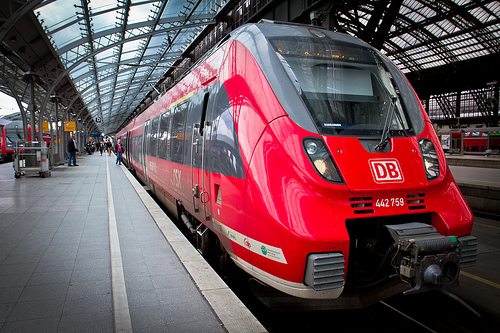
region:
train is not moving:
[117, 23, 479, 303]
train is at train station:
[114, 23, 484, 300]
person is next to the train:
[113, 138, 128, 165]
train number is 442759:
[113, 28, 483, 299]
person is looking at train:
[65, 133, 80, 167]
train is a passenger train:
[116, 21, 485, 310]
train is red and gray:
[121, 34, 483, 306]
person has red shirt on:
[113, 134, 125, 166]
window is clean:
[266, 33, 429, 138]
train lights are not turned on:
[127, 21, 483, 301]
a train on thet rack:
[90, 87, 404, 307]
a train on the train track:
[101, 2, 478, 305]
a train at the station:
[134, 26, 482, 321]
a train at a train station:
[87, 33, 467, 281]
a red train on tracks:
[100, 50, 475, 325]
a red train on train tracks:
[104, 28, 490, 303]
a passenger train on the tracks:
[129, 34, 458, 286]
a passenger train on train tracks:
[44, 70, 422, 317]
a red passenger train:
[107, 48, 497, 252]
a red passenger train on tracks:
[116, 34, 365, 264]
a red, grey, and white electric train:
[85, 15, 478, 314]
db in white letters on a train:
[368, 157, 406, 185]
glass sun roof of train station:
[7, 0, 495, 142]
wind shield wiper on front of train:
[366, 56, 396, 161]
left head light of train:
[303, 130, 347, 195]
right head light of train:
[412, 130, 446, 185]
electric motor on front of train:
[387, 213, 467, 300]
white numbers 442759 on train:
[369, 190, 416, 212]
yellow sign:
[63, 118, 75, 131]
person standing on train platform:
[63, 132, 83, 164]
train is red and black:
[106, 16, 480, 313]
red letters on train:
[369, 154, 401, 184]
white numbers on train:
[372, 194, 409, 214]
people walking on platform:
[61, 124, 127, 169]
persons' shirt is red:
[111, 139, 128, 165]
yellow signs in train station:
[36, 117, 81, 134]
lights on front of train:
[296, 128, 443, 188]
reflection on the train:
[110, 24, 422, 256]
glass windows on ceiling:
[35, 4, 496, 131]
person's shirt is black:
[65, 130, 77, 170]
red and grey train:
[115, 24, 475, 303]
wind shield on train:
[282, 55, 409, 130]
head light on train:
[306, 142, 340, 182]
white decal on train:
[372, 162, 400, 182]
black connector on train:
[391, 227, 455, 292]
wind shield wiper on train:
[378, 93, 399, 152]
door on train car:
[196, 91, 209, 211]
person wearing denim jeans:
[68, 133, 78, 168]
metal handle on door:
[189, 121, 201, 216]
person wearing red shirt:
[113, 138, 123, 163]